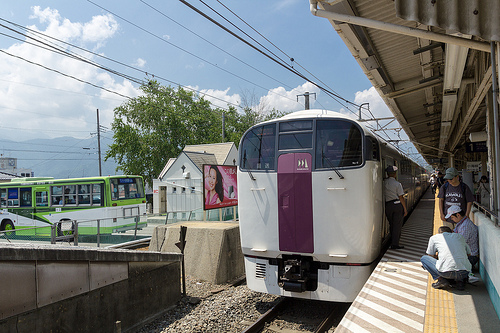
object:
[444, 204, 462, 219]
hat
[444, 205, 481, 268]
man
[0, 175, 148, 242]
bus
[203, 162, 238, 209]
billboard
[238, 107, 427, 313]
train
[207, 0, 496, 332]
station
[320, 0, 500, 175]
overhang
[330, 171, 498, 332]
platform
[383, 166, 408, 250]
driver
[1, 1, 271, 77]
lines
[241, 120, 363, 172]
windshield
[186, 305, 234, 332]
gravel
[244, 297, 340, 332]
train rails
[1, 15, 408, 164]
clouds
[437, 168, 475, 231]
man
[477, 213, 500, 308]
wall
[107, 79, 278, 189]
tree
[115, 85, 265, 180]
leaves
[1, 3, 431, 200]
sky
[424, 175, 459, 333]
stripe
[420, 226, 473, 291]
men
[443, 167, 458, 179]
hat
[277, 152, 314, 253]
door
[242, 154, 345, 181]
windshield wiper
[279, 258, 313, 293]
connector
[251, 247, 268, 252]
handle bar